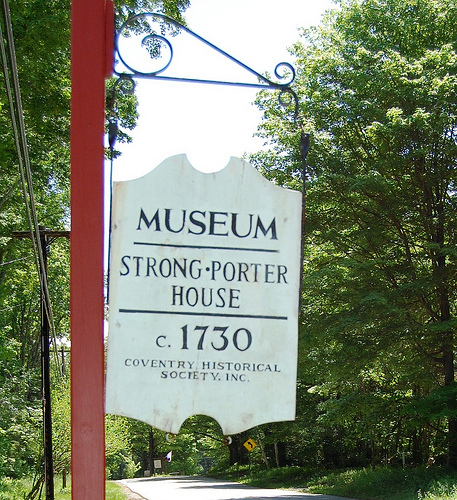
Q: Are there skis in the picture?
A: No, there are no skis.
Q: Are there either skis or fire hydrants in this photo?
A: No, there are no skis or fire hydrants.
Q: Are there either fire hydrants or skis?
A: No, there are no skis or fire hydrants.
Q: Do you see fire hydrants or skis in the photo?
A: No, there are no skis or fire hydrants.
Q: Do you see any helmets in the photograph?
A: No, there are no helmets.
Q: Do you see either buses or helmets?
A: No, there are no helmets or buses.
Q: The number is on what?
A: The number is on the sign.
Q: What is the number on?
A: The number is on the sign.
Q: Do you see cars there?
A: No, there are no cars.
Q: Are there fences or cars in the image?
A: No, there are no cars or fences.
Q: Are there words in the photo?
A: Yes, there are words.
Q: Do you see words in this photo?
A: Yes, there are words.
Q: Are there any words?
A: Yes, there are words.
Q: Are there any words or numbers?
A: Yes, there are words.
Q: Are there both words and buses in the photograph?
A: No, there are words but no buses.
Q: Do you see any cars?
A: No, there are no cars.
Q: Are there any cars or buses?
A: No, there are no cars or buses.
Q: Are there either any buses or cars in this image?
A: No, there are no cars or buses.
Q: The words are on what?
A: The words are on the sign.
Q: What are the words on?
A: The words are on the sign.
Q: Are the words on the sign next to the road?
A: Yes, the words are on the sign.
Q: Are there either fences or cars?
A: No, there are no fences or cars.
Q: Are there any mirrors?
A: No, there are no mirrors.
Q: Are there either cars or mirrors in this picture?
A: No, there are no mirrors or cars.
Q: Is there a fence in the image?
A: No, there are no fences.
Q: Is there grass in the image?
A: Yes, there is grass.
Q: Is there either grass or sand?
A: Yes, there is grass.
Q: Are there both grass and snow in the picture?
A: No, there is grass but no snow.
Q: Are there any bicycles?
A: No, there are no bicycles.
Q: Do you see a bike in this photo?
A: No, there are no bikes.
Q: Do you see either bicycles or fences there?
A: No, there are no bicycles or fences.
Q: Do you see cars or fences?
A: No, there are no cars or fences.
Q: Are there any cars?
A: No, there are no cars.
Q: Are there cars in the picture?
A: No, there are no cars.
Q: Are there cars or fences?
A: No, there are no cars or fences.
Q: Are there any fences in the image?
A: No, there are no fences.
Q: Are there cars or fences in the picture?
A: No, there are no fences or cars.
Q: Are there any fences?
A: No, there are no fences.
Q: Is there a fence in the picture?
A: No, there are no fences.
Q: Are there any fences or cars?
A: No, there are no fences or cars.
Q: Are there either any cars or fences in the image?
A: No, there are no fences or cars.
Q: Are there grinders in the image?
A: No, there are no grinders.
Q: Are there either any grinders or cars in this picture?
A: No, there are no grinders or cars.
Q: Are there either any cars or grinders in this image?
A: No, there are no grinders or cars.